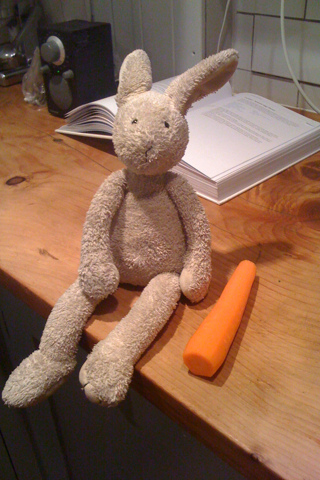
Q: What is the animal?
A: A fuzzy stuffed rabbit.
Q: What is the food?
A: A peeled orange carrot.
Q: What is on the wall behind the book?
A: White tiles.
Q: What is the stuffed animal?
A: A rabbit.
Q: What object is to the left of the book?
A: A speaker.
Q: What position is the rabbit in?
A: Sitting.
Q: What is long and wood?
A: The table.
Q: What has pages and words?
A: The book.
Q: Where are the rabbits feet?
A: Hanging off the table.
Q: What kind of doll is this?
A: Rabbit.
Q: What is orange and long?
A: Carrot.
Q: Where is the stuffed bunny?
A: Table near carrot.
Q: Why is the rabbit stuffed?
A: Toy animal.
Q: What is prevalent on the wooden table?
A: Knots in tree wood.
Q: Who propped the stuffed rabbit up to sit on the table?
A: Human being.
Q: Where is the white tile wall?
A: Background.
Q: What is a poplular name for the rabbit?
A: Bunny rabbit.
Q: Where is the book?
A: On the table.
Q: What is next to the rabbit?
A: A carrot.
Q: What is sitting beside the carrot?
A: Bunny.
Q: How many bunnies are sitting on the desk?
A: 1.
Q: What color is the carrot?
A: Orange.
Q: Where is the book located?
A: Behind the bunny.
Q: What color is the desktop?
A: Brown.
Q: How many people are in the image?
A: 0.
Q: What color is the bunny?
A: Tan.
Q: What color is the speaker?
A: Black.